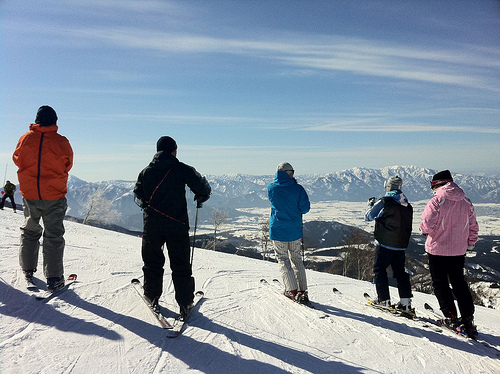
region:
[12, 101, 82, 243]
A person in an orange jacket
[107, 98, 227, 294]
A person in a black jacket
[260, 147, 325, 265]
A person in a blue jacket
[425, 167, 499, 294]
A person in a pink jacket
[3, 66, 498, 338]
People at a ski resort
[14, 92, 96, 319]
A person on skis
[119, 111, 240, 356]
A person on skis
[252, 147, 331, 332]
A person on skis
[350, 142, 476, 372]
Two people on skis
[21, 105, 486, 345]
Five people on skis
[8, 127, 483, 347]
Five skiers overlooking a slope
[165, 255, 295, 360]
Ski tracks in the snow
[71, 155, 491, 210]
A long mountain range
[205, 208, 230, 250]
A bare leafless tree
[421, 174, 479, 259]
A woman in a pink jacket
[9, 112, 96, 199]
A black stripe down the back of an orange jacket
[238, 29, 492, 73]
Streaks of white clouds across the sky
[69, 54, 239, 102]
A blue sky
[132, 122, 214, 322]
A skier in a black ski outfit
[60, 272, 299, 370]
Shadows of skiers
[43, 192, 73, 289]
the leg of a person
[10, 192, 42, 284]
the leg of a person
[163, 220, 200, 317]
the leg of a person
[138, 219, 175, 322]
the leg of a person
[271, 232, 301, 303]
the leg of a person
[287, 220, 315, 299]
the leg of a person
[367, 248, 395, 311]
the leg of a person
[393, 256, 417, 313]
the leg of a person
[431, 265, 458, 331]
the leg of a person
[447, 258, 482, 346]
the leg of a person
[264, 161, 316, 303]
a woman in a blue coat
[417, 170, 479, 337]
a woman in a pink coat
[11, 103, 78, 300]
a man in an orange coat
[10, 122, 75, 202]
an orange coat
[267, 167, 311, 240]
a blue coat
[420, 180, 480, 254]
a pink coat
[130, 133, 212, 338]
a man with a black hat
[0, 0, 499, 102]
white clouds can be seen in the blue sky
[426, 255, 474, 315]
black pants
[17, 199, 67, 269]
grey pants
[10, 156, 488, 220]
Mountains in the background.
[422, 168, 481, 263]
Skier in pink jacket.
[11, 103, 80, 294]
Skier in red jacket.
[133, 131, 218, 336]
Skier in black snowsuit.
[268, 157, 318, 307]
Skier in blue jacket.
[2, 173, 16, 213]
Man in the distance.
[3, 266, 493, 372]
Shadows on the ground from the skiers.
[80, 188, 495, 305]
Trees in the background.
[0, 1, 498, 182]
Blue sky in the background.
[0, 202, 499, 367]
Snow on the ground.